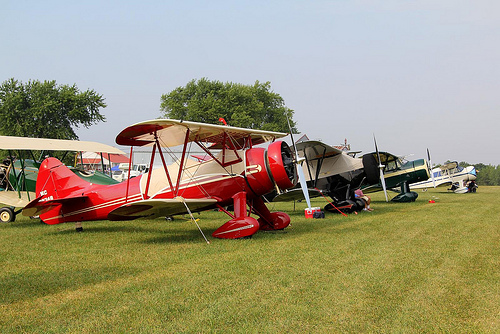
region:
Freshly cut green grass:
[1, 263, 125, 332]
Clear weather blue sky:
[316, 1, 498, 124]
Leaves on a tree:
[0, 74, 108, 135]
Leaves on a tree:
[166, 73, 312, 124]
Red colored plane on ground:
[32, 118, 310, 246]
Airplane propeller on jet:
[273, 123, 332, 208]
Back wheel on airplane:
[0, 204, 30, 231]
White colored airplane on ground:
[430, 156, 482, 199]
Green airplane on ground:
[365, 143, 438, 210]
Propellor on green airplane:
[417, 148, 436, 188]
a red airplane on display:
[0, 118, 310, 238]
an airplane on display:
[279, 139, 387, 216]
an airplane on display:
[360, 150, 435, 203]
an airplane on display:
[407, 163, 480, 191]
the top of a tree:
[160, 80, 300, 135]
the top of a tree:
[0, 75, 107, 140]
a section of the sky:
[1, 0, 496, 171]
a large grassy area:
[1, 184, 499, 331]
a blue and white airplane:
[412, 163, 480, 194]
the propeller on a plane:
[281, 107, 311, 212]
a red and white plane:
[21, 114, 313, 236]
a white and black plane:
[276, 132, 392, 215]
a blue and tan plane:
[357, 148, 432, 201]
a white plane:
[387, 160, 479, 191]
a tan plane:
[0, 138, 122, 220]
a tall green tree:
[157, 75, 295, 150]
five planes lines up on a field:
[0, 121, 480, 241]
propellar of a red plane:
[283, 108, 315, 208]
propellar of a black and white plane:
[371, 139, 394, 201]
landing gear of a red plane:
[218, 210, 284, 235]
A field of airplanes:
[23, 106, 498, 259]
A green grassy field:
[122, 223, 444, 310]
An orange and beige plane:
[33, 136, 291, 241]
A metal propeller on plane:
[276, 107, 331, 210]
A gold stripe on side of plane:
[47, 160, 289, 207]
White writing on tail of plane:
[37, 178, 60, 210]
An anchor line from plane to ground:
[176, 194, 241, 264]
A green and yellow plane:
[372, 137, 443, 198]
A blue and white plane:
[433, 152, 489, 197]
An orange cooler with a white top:
[303, 198, 334, 222]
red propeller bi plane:
[258, 158, 283, 199]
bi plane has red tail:
[42, 159, 69, 233]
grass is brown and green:
[183, 279, 262, 324]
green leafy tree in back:
[198, 105, 269, 132]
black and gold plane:
[401, 158, 416, 204]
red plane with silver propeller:
[278, 136, 309, 209]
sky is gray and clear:
[121, 59, 183, 97]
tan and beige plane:
[326, 159, 355, 206]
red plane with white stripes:
[94, 193, 162, 230]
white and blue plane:
[441, 160, 493, 211]